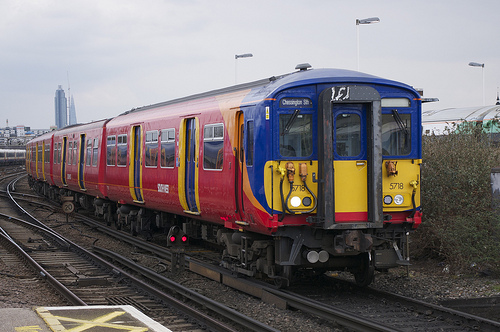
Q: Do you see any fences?
A: No, there are no fences.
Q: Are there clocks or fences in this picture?
A: No, there are no fences or clocks.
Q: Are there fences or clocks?
A: No, there are no fences or clocks.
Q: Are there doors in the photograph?
A: Yes, there is a door.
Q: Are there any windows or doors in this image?
A: Yes, there is a door.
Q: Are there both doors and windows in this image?
A: Yes, there are both a door and a window.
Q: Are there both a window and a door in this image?
A: Yes, there are both a door and a window.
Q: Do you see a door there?
A: Yes, there is a door.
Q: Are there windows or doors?
A: Yes, there is a door.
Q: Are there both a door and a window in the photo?
A: Yes, there are both a door and a window.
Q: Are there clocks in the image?
A: No, there are no clocks.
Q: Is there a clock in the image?
A: No, there are no clocks.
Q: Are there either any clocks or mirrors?
A: No, there are no clocks or mirrors.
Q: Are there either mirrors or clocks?
A: No, there are no clocks or mirrors.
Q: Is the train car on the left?
A: Yes, the train car is on the left of the image.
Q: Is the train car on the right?
A: No, the train car is on the left of the image.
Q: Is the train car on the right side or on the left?
A: The train car is on the left of the image.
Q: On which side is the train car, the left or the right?
A: The train car is on the left of the image.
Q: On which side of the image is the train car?
A: The train car is on the left of the image.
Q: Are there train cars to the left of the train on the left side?
A: No, the train car is to the right of the train.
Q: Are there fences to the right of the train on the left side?
A: No, there is a train car to the right of the train.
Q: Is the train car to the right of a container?
A: No, the train car is to the right of the train.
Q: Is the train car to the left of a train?
A: No, the train car is to the right of a train.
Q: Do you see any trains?
A: Yes, there is a train.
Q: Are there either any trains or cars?
A: Yes, there is a train.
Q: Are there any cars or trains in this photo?
A: Yes, there is a train.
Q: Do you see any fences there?
A: No, there are no fences.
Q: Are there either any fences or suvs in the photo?
A: No, there are no fences or suvs.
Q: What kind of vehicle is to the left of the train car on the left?
A: The vehicle is a train.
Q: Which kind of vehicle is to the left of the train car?
A: The vehicle is a train.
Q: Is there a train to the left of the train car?
A: Yes, there is a train to the left of the train car.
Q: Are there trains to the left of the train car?
A: Yes, there is a train to the left of the train car.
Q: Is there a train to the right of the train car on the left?
A: No, the train is to the left of the train car.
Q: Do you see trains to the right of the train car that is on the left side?
A: No, the train is to the left of the train car.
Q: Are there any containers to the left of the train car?
A: No, there is a train to the left of the train car.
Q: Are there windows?
A: Yes, there are windows.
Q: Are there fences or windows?
A: Yes, there are windows.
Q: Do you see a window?
A: Yes, there are windows.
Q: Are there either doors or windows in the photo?
A: Yes, there are windows.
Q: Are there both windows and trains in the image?
A: Yes, there are both windows and a train.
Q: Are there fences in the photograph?
A: No, there are no fences.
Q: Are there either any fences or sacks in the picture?
A: No, there are no fences or sacks.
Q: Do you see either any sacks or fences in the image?
A: No, there are no fences or sacks.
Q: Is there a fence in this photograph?
A: No, there are no fences.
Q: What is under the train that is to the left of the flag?
A: The train tracks are under the train.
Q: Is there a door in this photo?
A: Yes, there is a door.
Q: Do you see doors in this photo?
A: Yes, there is a door.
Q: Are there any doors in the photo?
A: Yes, there is a door.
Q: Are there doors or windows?
A: Yes, there is a door.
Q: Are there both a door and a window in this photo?
A: Yes, there are both a door and a window.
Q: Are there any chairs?
A: No, there are no chairs.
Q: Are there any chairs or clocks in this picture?
A: No, there are no chairs or clocks.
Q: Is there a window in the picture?
A: Yes, there are windows.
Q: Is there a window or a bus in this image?
A: Yes, there are windows.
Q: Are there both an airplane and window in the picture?
A: No, there are windows but no airplanes.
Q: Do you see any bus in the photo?
A: No, there are no buses.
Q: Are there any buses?
A: No, there are no buses.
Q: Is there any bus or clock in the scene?
A: No, there are no buses or clocks.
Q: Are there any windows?
A: Yes, there are windows.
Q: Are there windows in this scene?
A: Yes, there are windows.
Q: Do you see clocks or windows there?
A: Yes, there are windows.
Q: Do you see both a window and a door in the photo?
A: Yes, there are both a window and a door.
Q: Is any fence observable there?
A: No, there are no fences.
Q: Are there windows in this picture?
A: Yes, there are windows.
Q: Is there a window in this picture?
A: Yes, there are windows.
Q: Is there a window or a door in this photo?
A: Yes, there are windows.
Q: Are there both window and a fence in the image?
A: No, there are windows but no fences.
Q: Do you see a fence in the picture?
A: No, there are no fences.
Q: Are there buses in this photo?
A: No, there are no buses.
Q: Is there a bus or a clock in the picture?
A: No, there are no buses or clocks.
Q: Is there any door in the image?
A: Yes, there is a door.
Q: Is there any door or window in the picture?
A: Yes, there is a door.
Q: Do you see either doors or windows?
A: Yes, there is a door.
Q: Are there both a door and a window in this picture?
A: Yes, there are both a door and a window.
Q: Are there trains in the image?
A: Yes, there is a train.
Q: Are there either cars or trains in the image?
A: Yes, there is a train.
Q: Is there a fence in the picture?
A: No, there are no fences.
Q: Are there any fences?
A: No, there are no fences.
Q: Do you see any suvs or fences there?
A: No, there are no fences or suvs.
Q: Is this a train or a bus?
A: This is a train.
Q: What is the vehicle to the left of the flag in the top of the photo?
A: The vehicle is a train.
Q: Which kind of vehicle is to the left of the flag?
A: The vehicle is a train.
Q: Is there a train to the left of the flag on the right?
A: Yes, there is a train to the left of the flag.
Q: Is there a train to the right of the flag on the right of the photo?
A: No, the train is to the left of the flag.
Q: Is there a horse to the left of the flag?
A: No, there is a train to the left of the flag.